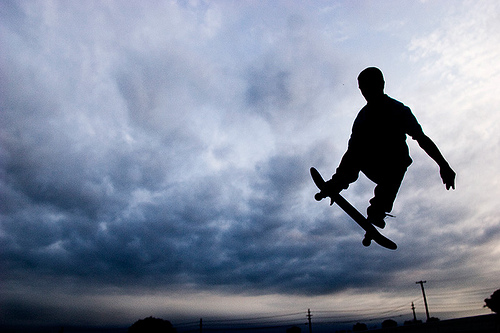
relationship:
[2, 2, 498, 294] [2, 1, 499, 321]
clouds in sky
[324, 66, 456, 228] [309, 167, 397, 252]
boy holding skateboard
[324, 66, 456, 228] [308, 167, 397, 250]
boy doing tricks on board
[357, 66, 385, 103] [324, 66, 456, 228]
head of boy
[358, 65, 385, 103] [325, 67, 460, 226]
head in shadow man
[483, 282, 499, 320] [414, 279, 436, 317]
tree near pole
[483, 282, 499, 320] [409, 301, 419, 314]
tree near pole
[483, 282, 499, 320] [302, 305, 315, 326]
tree near pole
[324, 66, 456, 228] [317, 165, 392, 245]
boy holding board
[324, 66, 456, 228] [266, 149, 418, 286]
boy on skateboard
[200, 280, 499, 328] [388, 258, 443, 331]
lines on poles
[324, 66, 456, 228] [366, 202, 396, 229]
boy wearing untied shoe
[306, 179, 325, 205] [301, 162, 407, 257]
wheel on skateboard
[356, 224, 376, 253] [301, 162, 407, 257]
wheel on skateboard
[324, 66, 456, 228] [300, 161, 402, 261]
boy looking down at board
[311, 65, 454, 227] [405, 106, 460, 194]
boy has arm